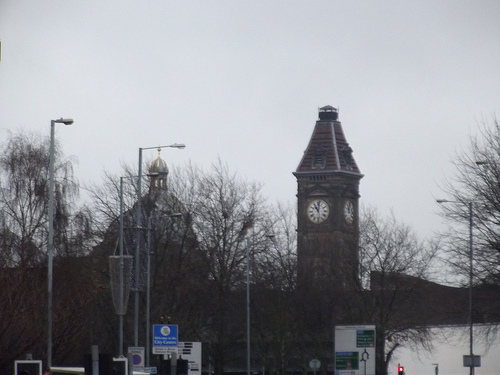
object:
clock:
[307, 199, 331, 224]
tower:
[291, 104, 364, 290]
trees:
[0, 112, 499, 373]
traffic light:
[396, 366, 405, 374]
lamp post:
[436, 198, 481, 374]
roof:
[318, 105, 339, 121]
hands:
[316, 200, 321, 212]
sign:
[463, 354, 481, 367]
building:
[1, 104, 378, 374]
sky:
[0, 0, 499, 372]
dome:
[102, 144, 197, 250]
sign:
[151, 323, 180, 355]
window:
[311, 143, 327, 171]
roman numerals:
[316, 217, 321, 224]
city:
[0, 1, 500, 373]